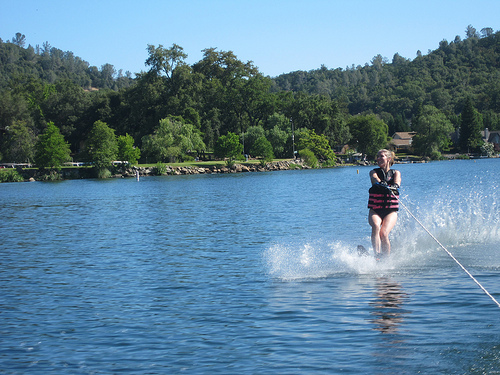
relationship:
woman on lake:
[363, 138, 428, 300] [135, 293, 253, 331]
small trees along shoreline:
[21, 129, 204, 164] [220, 166, 314, 174]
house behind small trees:
[392, 126, 416, 154] [21, 129, 204, 164]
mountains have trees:
[375, 46, 478, 103] [343, 69, 370, 100]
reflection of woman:
[363, 274, 416, 342] [363, 138, 428, 300]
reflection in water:
[363, 274, 416, 342] [448, 162, 499, 184]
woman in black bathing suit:
[363, 138, 428, 300] [368, 168, 399, 211]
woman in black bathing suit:
[363, 138, 428, 300] [376, 204, 396, 222]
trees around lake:
[145, 46, 283, 126] [135, 293, 253, 331]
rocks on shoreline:
[276, 160, 309, 172] [220, 166, 314, 174]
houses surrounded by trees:
[394, 118, 500, 160] [145, 46, 283, 126]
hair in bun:
[378, 148, 388, 152] [391, 148, 399, 164]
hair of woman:
[378, 148, 388, 152] [363, 138, 428, 300]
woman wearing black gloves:
[363, 138, 428, 300] [376, 174, 408, 192]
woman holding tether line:
[363, 138, 428, 300] [412, 209, 480, 292]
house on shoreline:
[392, 126, 416, 154] [220, 166, 314, 174]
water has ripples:
[448, 162, 499, 184] [126, 189, 170, 217]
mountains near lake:
[375, 46, 478, 103] [135, 293, 253, 331]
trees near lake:
[145, 46, 283, 126] [135, 293, 253, 331]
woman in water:
[363, 138, 428, 300] [448, 162, 499, 184]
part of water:
[267, 194, 314, 198] [448, 162, 499, 184]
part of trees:
[169, 87, 225, 104] [145, 46, 283, 126]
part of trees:
[267, 194, 314, 198] [145, 46, 283, 126]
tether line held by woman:
[412, 209, 480, 292] [363, 138, 428, 300]